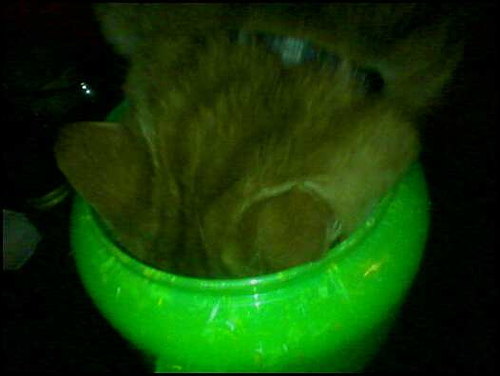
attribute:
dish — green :
[70, 164, 431, 374]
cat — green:
[78, 27, 413, 279]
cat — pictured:
[85, 40, 390, 234]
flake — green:
[54, 181, 491, 374]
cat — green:
[39, 5, 432, 283]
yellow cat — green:
[49, 0, 486, 280]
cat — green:
[56, 1, 498, 255]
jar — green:
[51, 137, 451, 367]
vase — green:
[66, 158, 428, 374]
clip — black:
[276, 40, 373, 89]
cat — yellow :
[53, 0, 483, 280]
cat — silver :
[60, 9, 451, 264]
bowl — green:
[65, 204, 472, 353]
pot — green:
[62, 160, 435, 374]